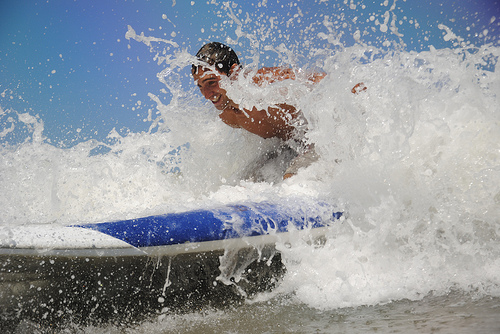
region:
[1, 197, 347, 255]
The surfboard the man is riding on.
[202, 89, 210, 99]
The nose of the man.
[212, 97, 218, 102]
The teeth in the man's mouth.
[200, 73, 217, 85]
The eyebrow of the man.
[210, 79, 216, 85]
The right eye of the man.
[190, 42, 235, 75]
The man's short black hair.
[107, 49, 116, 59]
drop of white water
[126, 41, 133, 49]
drop of white water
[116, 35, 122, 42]
drop of white water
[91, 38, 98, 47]
drop of white water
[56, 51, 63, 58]
drop of white water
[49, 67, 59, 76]
drop of white water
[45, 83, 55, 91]
drop of white water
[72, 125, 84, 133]
drop of white water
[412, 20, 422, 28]
drop of white water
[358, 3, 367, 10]
drop of white water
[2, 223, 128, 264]
The white tip of the surfboard.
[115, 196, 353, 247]
The blue portion of the surfboard.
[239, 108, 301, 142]
The chest of the surfer.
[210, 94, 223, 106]
The mouth of the surfer.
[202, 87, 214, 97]
The nose of the man.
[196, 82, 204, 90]
The left eye of the man.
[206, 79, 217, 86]
The right eye of the man.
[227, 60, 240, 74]
The tip of the man's ear.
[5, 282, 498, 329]
The water under the surfboard.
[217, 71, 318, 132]
The shoulders of the man.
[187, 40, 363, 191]
surfer kneels on surfboard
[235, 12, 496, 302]
white frothy water around the surfer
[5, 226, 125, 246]
white tip on board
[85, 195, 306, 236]
blue body of the surfboard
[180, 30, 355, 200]
surfer leans forward on the board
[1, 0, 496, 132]
sky is clear blue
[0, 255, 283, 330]
drops of splashed water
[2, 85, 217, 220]
splashed water behind the board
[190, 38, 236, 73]
dark hair on the surfer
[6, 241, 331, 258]
grey bottom of the surfboard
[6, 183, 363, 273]
blue and white surfboard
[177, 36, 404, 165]
a man that surfing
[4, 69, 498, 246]
water that is splashing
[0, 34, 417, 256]
a man surfing in water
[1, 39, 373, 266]
a man surfing in the ocean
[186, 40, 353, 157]
a man that is smiling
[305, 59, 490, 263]
white water splashing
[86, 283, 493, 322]
calm ocean water below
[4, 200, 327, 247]
a blue and white board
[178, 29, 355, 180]
the person is in water